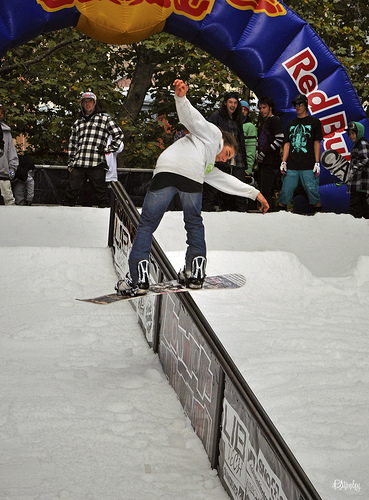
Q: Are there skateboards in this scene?
A: No, there are no skateboards.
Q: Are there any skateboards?
A: No, there are no skateboards.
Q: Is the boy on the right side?
A: Yes, the boy is on the right of the image.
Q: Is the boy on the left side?
A: No, the boy is on the right of the image.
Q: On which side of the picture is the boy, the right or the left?
A: The boy is on the right of the image.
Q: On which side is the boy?
A: The boy is on the right of the image.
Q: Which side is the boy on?
A: The boy is on the right of the image.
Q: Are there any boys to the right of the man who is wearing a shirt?
A: Yes, there is a boy to the right of the man.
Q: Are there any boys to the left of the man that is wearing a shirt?
A: No, the boy is to the right of the man.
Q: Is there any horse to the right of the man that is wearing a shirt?
A: No, there is a boy to the right of the man.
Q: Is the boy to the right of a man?
A: Yes, the boy is to the right of a man.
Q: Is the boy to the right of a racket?
A: No, the boy is to the right of a man.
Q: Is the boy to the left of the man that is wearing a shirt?
A: No, the boy is to the right of the man.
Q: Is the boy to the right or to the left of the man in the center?
A: The boy is to the right of the man.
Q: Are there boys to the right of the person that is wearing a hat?
A: Yes, there is a boy to the right of the person.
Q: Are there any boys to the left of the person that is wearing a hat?
A: No, the boy is to the right of the person.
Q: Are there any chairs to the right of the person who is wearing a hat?
A: No, there is a boy to the right of the person.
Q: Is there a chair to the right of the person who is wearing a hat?
A: No, there is a boy to the right of the person.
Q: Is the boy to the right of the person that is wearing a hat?
A: Yes, the boy is to the right of the person.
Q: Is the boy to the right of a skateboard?
A: No, the boy is to the right of the person.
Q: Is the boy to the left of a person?
A: No, the boy is to the right of a person.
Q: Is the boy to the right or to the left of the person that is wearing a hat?
A: The boy is to the right of the person.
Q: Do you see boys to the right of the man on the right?
A: Yes, there is a boy to the right of the man.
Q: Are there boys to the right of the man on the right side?
A: Yes, there is a boy to the right of the man.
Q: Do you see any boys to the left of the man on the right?
A: No, the boy is to the right of the man.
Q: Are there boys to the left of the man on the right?
A: No, the boy is to the right of the man.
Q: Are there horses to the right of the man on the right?
A: No, there is a boy to the right of the man.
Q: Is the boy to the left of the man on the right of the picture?
A: No, the boy is to the right of the man.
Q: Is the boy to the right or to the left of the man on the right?
A: The boy is to the right of the man.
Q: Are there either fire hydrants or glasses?
A: No, there are no glasses or fire hydrants.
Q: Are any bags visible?
A: No, there are no bags.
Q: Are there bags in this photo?
A: No, there are no bags.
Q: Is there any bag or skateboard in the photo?
A: No, there are no bags or skateboards.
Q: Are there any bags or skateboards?
A: No, there are no bags or skateboards.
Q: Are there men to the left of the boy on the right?
A: Yes, there is a man to the left of the boy.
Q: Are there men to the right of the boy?
A: No, the man is to the left of the boy.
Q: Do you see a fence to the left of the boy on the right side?
A: No, there is a man to the left of the boy.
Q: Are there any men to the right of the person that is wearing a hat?
A: Yes, there is a man to the right of the person.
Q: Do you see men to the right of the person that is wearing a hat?
A: Yes, there is a man to the right of the person.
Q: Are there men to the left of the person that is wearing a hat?
A: No, the man is to the right of the person.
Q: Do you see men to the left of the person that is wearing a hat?
A: No, the man is to the right of the person.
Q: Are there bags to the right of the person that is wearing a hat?
A: No, there is a man to the right of the person.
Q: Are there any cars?
A: No, there are no cars.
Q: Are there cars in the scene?
A: No, there are no cars.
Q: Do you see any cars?
A: No, there are no cars.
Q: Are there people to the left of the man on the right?
A: Yes, there is a person to the left of the man.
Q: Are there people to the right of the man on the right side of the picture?
A: No, the person is to the left of the man.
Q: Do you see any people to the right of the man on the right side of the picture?
A: No, the person is to the left of the man.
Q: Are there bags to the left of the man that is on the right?
A: No, there is a person to the left of the man.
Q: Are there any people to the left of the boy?
A: Yes, there is a person to the left of the boy.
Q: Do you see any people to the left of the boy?
A: Yes, there is a person to the left of the boy.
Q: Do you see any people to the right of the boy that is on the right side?
A: No, the person is to the left of the boy.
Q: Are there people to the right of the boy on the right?
A: No, the person is to the left of the boy.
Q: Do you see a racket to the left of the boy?
A: No, there is a person to the left of the boy.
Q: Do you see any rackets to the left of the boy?
A: No, there is a person to the left of the boy.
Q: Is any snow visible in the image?
A: Yes, there is snow.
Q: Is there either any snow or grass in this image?
A: Yes, there is snow.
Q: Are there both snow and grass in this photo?
A: No, there is snow but no grass.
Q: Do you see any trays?
A: No, there are no trays.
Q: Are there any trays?
A: No, there are no trays.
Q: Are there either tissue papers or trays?
A: No, there are no trays or tissue papers.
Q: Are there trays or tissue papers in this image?
A: No, there are no trays or tissue papers.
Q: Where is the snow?
A: The snow is on the ground.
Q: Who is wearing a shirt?
A: The man is wearing a shirt.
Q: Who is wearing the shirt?
A: The man is wearing a shirt.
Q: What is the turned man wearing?
A: The man is wearing a shirt.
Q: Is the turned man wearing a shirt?
A: Yes, the man is wearing a shirt.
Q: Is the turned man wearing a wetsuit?
A: No, the man is wearing a shirt.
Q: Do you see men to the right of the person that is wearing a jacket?
A: Yes, there is a man to the right of the person.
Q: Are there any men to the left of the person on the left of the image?
A: No, the man is to the right of the person.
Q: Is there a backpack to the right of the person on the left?
A: No, there is a man to the right of the person.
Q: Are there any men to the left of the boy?
A: Yes, there is a man to the left of the boy.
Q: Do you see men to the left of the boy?
A: Yes, there is a man to the left of the boy.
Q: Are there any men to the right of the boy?
A: No, the man is to the left of the boy.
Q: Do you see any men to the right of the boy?
A: No, the man is to the left of the boy.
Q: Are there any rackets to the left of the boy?
A: No, there is a man to the left of the boy.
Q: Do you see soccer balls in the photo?
A: No, there are no soccer balls.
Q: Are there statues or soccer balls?
A: No, there are no soccer balls or statues.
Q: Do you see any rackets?
A: No, there are no rackets.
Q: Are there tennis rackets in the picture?
A: No, there are no tennis rackets.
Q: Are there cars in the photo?
A: No, there are no cars.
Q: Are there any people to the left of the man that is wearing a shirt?
A: Yes, there is a person to the left of the man.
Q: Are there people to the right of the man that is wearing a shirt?
A: No, the person is to the left of the man.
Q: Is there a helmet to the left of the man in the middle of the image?
A: No, there is a person to the left of the man.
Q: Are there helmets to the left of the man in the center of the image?
A: No, there is a person to the left of the man.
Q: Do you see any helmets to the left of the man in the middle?
A: No, there is a person to the left of the man.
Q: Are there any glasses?
A: No, there are no glasses.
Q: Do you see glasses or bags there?
A: No, there are no glasses or bags.